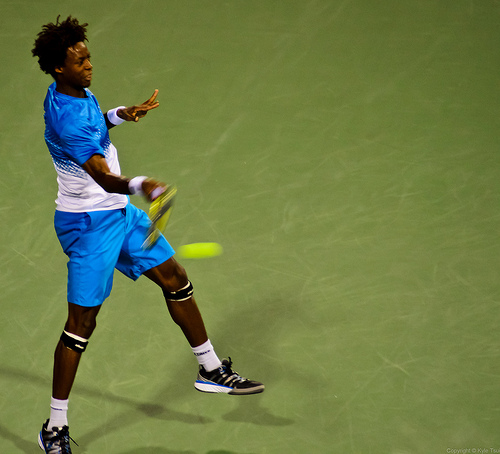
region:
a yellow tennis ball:
[175, 235, 226, 264]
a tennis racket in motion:
[141, 180, 178, 259]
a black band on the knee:
[55, 326, 94, 352]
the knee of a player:
[164, 263, 192, 288]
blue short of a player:
[66, 225, 120, 301]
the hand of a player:
[123, 90, 169, 124]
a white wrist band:
[106, 101, 123, 121]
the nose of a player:
[83, 60, 94, 70]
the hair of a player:
[36, 21, 73, 56]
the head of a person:
[31, 20, 101, 87]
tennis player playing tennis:
[35, 22, 260, 424]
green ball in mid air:
[184, 233, 221, 259]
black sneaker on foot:
[194, 365, 272, 401]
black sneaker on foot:
[31, 417, 98, 452]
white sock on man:
[194, 334, 224, 364]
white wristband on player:
[127, 168, 155, 196]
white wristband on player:
[102, 93, 124, 123]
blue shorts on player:
[58, 198, 185, 293]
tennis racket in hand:
[145, 187, 188, 257]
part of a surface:
[396, 300, 409, 310]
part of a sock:
[206, 358, 211, 373]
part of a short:
[67, 262, 87, 278]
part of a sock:
[198, 343, 202, 352]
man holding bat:
[126, 168, 179, 253]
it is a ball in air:
[174, 232, 225, 267]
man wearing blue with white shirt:
[26, 80, 137, 211]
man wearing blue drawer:
[39, 194, 182, 308]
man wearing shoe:
[41, 358, 283, 453]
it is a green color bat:
[144, 183, 181, 259]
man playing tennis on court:
[21, 18, 303, 452]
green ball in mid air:
[173, 230, 219, 264]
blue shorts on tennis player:
[47, 215, 178, 290]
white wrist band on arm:
[120, 168, 147, 190]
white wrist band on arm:
[105, 99, 130, 135]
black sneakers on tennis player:
[193, 350, 283, 405]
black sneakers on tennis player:
[25, 407, 69, 449]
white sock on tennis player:
[185, 328, 228, 368]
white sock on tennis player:
[45, 388, 77, 410]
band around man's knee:
[170, 274, 199, 304]